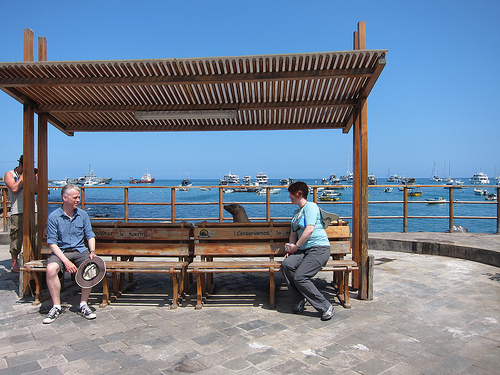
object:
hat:
[75, 256, 106, 289]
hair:
[288, 180, 309, 199]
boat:
[129, 168, 155, 184]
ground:
[415, 133, 458, 178]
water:
[0, 178, 499, 233]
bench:
[186, 219, 359, 309]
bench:
[20, 221, 195, 308]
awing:
[0, 48, 388, 136]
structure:
[0, 20, 387, 310]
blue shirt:
[47, 207, 96, 256]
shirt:
[291, 201, 331, 250]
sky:
[0, 0, 500, 178]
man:
[42, 184, 106, 324]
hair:
[61, 184, 81, 200]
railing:
[47, 185, 497, 233]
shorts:
[46, 248, 91, 280]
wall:
[307, 113, 374, 205]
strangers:
[281, 180, 335, 321]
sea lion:
[224, 204, 251, 223]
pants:
[281, 245, 331, 312]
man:
[4, 155, 38, 273]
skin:
[288, 190, 299, 205]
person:
[281, 181, 335, 320]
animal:
[223, 204, 250, 223]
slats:
[0, 49, 389, 133]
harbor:
[1, 179, 497, 372]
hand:
[89, 252, 97, 260]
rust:
[197, 229, 292, 239]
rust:
[94, 231, 151, 237]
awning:
[0, 49, 388, 137]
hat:
[17, 155, 36, 165]